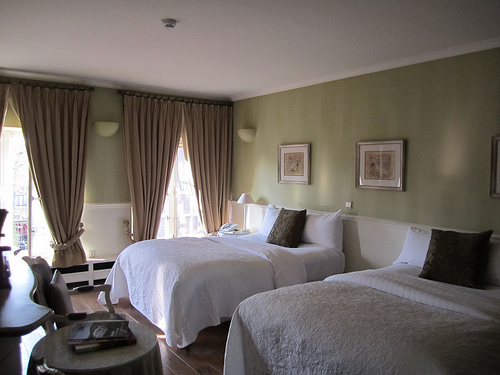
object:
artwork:
[355, 138, 407, 191]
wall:
[230, 46, 500, 233]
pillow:
[418, 229, 493, 292]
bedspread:
[222, 269, 500, 375]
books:
[66, 311, 136, 354]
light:
[94, 121, 120, 137]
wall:
[0, 76, 133, 260]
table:
[219, 232, 252, 235]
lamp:
[237, 193, 255, 233]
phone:
[219, 223, 238, 235]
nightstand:
[217, 231, 251, 236]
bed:
[221, 226, 499, 374]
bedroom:
[0, 0, 500, 375]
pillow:
[266, 206, 307, 248]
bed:
[97, 204, 346, 352]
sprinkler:
[162, 19, 176, 29]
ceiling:
[0, 0, 500, 103]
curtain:
[9, 83, 90, 269]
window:
[0, 126, 56, 267]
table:
[30, 321, 156, 370]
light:
[238, 128, 257, 142]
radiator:
[50, 260, 116, 290]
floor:
[0, 290, 231, 375]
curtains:
[122, 90, 185, 242]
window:
[156, 138, 207, 240]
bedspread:
[97, 236, 308, 349]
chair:
[22, 256, 115, 337]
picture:
[277, 143, 312, 185]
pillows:
[261, 203, 281, 236]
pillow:
[302, 209, 344, 257]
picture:
[487, 131, 499, 199]